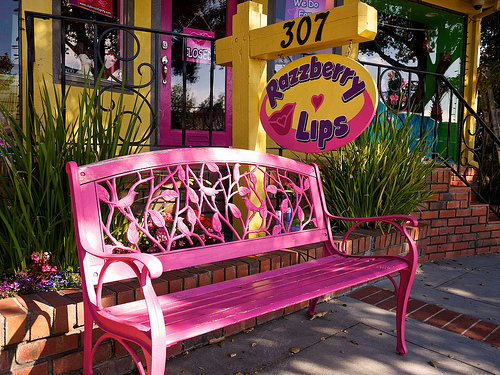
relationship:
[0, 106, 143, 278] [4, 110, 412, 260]
grass in garden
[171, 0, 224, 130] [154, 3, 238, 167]
window on door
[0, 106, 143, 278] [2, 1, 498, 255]
grass on building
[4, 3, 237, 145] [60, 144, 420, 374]
building behind bench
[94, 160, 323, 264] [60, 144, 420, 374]
pattern on bench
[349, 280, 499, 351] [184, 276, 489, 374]
brick on sidewalk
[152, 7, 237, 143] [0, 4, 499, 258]
door to business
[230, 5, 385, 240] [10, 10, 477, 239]
sign for business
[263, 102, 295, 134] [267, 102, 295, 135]
lips has lips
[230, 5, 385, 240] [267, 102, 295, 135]
sign has lips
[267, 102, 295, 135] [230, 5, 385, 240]
lips on sign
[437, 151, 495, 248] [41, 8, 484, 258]
steps leading to business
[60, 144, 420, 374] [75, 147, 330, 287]
bench has back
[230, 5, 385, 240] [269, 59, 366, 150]
sign says razzberry lips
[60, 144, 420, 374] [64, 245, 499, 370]
bench on ground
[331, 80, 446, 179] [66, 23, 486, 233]
plants in garden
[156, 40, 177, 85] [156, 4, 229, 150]
handle on door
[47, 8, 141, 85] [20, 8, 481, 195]
window on building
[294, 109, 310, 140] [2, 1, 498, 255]
letter on building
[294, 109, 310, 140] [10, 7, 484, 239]
letter on building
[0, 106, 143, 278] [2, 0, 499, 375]
grass on building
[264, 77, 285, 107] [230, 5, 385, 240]
alphabet on sign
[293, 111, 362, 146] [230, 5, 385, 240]
alphabet on sign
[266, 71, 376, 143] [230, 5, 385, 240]
alphabet on sign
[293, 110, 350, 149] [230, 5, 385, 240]
alphabet on sign